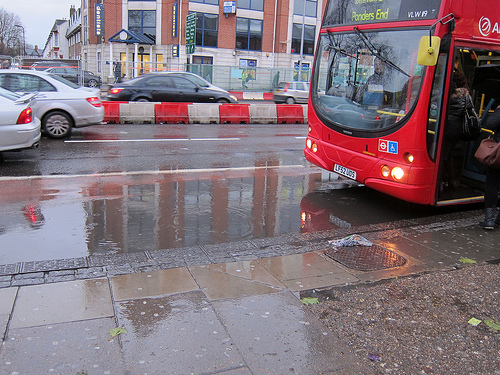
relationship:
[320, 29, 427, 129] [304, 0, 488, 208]
windshield on bus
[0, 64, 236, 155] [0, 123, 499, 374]
vehicles on ground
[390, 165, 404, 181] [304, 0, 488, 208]
headlight on bus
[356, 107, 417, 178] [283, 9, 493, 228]
sign on bus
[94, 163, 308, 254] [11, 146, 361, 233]
cement on road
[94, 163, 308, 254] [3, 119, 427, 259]
cement on road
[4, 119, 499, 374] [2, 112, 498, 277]
cement on road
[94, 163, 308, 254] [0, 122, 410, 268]
cement on road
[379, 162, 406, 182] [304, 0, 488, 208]
headlight on bus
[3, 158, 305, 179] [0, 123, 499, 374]
line on ground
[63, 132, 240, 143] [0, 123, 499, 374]
line on ground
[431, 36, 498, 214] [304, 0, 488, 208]
door on bus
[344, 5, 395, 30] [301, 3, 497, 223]
sign for bus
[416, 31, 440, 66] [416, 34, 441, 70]
yellow back of mirror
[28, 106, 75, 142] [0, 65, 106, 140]
wheel of car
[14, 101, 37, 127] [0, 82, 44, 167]
tail light of car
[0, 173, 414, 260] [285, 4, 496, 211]
puddle in front of bus